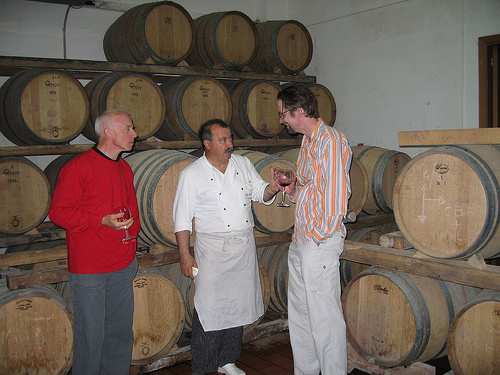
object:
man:
[275, 82, 354, 375]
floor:
[139, 325, 368, 375]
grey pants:
[68, 260, 136, 374]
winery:
[0, 0, 498, 374]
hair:
[91, 111, 136, 140]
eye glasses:
[277, 106, 302, 117]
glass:
[274, 162, 295, 209]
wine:
[390, 142, 498, 257]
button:
[210, 178, 214, 181]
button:
[219, 192, 222, 195]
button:
[223, 208, 226, 211]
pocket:
[306, 232, 331, 260]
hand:
[305, 228, 328, 248]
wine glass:
[275, 166, 295, 207]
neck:
[281, 190, 285, 201]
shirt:
[292, 117, 351, 246]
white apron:
[192, 230, 267, 333]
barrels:
[250, 18, 316, 73]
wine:
[274, 168, 294, 191]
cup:
[108, 199, 137, 246]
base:
[268, 200, 298, 207]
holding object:
[182, 259, 199, 280]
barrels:
[189, 11, 259, 73]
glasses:
[276, 111, 287, 121]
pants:
[287, 231, 344, 375]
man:
[175, 119, 269, 374]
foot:
[215, 362, 246, 374]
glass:
[110, 203, 138, 246]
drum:
[1, 60, 93, 153]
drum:
[84, 65, 168, 147]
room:
[2, 2, 498, 375]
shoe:
[218, 357, 248, 374]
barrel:
[390, 139, 499, 259]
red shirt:
[48, 149, 142, 275]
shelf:
[0, 135, 315, 155]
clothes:
[172, 152, 272, 332]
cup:
[276, 167, 294, 208]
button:
[236, 172, 238, 175]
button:
[244, 203, 247, 206]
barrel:
[102, 2, 197, 68]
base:
[143, 2, 196, 62]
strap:
[209, 11, 227, 65]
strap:
[196, 11, 212, 67]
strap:
[190, 11, 203, 68]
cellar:
[3, 2, 495, 375]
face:
[274, 98, 306, 135]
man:
[46, 112, 146, 371]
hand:
[181, 254, 199, 280]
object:
[191, 267, 199, 276]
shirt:
[174, 151, 272, 235]